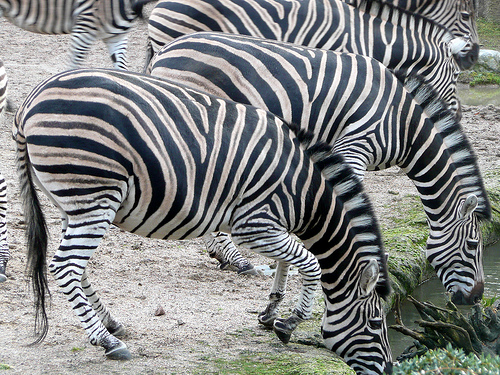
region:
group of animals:
[3, 4, 498, 366]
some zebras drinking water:
[3, 3, 497, 370]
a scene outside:
[16, 15, 483, 369]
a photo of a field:
[9, 11, 485, 353]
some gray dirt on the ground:
[1, 16, 457, 356]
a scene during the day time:
[2, 4, 483, 341]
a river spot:
[348, 182, 494, 367]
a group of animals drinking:
[0, 3, 495, 373]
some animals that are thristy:
[8, 4, 495, 354]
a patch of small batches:
[371, 281, 496, 372]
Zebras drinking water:
[10, 28, 495, 372]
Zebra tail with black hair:
[6, 140, 56, 351]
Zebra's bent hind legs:
[46, 214, 142, 358]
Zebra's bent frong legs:
[233, 218, 323, 359]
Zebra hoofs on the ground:
[76, 310, 146, 367]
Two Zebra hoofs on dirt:
[49, 265, 144, 365]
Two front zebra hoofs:
[250, 285, 315, 358]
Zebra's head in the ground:
[321, 311, 413, 371]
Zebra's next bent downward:
[271, 128, 411, 370]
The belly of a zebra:
[128, 175, 220, 258]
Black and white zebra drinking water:
[13, 68, 393, 373]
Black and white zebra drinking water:
[143, 33, 490, 305]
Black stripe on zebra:
[22, 98, 167, 232]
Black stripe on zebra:
[177, 100, 237, 240]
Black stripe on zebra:
[199, 103, 260, 236]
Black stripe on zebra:
[152, 55, 249, 105]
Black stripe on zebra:
[160, 41, 285, 121]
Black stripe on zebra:
[309, 50, 336, 137]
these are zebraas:
[1, 2, 496, 372]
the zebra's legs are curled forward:
[223, 197, 331, 372]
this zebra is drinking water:
[22, 64, 414, 373]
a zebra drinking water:
[142, 24, 499, 309]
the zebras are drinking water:
[23, 14, 495, 374]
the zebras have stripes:
[5, 26, 481, 374]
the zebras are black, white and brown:
[14, 27, 480, 373]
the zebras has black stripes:
[19, 69, 430, 371]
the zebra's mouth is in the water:
[434, 279, 497, 326]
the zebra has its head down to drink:
[15, 62, 407, 374]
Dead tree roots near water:
[386, 292, 498, 360]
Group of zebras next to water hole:
[3, 0, 496, 373]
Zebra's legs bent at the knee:
[231, 220, 321, 347]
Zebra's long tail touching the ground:
[13, 120, 55, 351]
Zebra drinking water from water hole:
[146, 32, 493, 309]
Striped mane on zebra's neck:
[293, 125, 393, 299]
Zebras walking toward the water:
[146, 2, 488, 124]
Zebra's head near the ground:
[320, 258, 396, 374]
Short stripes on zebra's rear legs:
[48, 210, 118, 340]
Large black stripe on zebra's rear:
[26, 98, 167, 225]